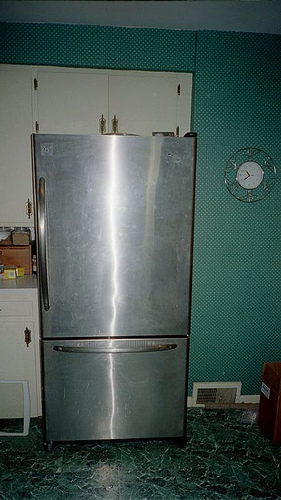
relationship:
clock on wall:
[223, 144, 279, 203] [190, 46, 275, 369]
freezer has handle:
[42, 340, 188, 443] [51, 343, 177, 352]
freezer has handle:
[29, 122, 197, 443] [37, 175, 53, 310]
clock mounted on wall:
[220, 144, 279, 204] [192, 25, 276, 403]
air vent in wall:
[193, 380, 241, 406] [188, 30, 280, 408]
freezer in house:
[29, 122, 197, 443] [1, 0, 278, 499]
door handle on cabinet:
[20, 325, 34, 350] [1, 298, 35, 416]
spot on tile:
[89, 465, 121, 487] [9, 391, 267, 498]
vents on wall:
[195, 389, 235, 407] [199, 92, 272, 404]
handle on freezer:
[35, 175, 51, 314] [29, 122, 197, 443]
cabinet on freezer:
[33, 67, 191, 135] [29, 122, 197, 443]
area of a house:
[3, 8, 225, 265] [1, 0, 278, 499]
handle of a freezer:
[35, 175, 51, 311] [29, 122, 197, 443]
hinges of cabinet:
[26, 76, 48, 134] [33, 67, 191, 135]